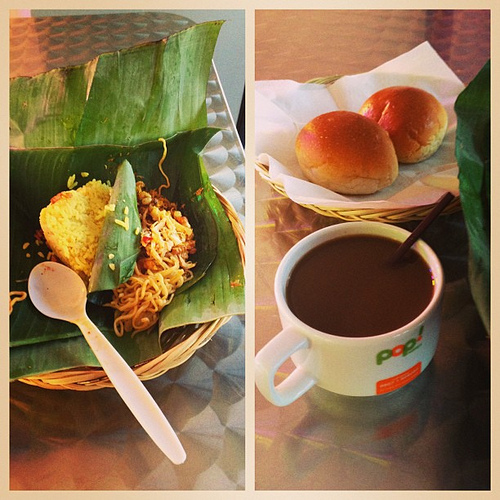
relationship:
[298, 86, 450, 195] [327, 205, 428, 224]
buns in basket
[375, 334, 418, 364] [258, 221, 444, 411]
logo on mug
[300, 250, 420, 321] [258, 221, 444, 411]
coffee in mug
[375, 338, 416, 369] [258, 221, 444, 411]
letters on mug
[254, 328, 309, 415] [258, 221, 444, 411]
handle of mug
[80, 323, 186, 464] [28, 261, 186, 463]
handle of spoon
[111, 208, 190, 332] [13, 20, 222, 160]
noodles on leave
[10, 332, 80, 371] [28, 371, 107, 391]
leave in basket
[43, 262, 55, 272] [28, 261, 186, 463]
food on spoon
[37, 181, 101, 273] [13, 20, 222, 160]
cronbread on leave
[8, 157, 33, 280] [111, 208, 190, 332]
leave under noodles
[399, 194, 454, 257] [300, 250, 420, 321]
straw in coffee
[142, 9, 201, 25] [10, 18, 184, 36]
edge of table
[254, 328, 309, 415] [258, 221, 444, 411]
handle of cup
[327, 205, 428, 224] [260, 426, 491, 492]
basket on table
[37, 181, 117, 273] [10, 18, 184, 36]
cronbread on table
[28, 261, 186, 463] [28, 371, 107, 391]
spoon in basket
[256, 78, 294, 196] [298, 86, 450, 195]
cloth under buns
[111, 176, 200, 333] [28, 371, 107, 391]
noodles in basket